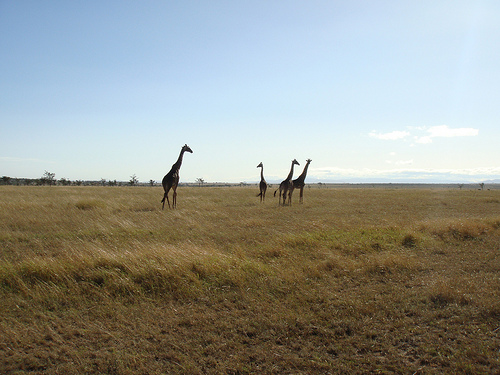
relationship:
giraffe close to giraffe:
[290, 157, 314, 206] [270, 151, 297, 203]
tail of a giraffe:
[272, 182, 281, 196] [275, 158, 300, 205]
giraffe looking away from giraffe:
[255, 160, 271, 201] [277, 149, 298, 207]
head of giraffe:
[179, 142, 193, 156] [159, 134, 200, 206]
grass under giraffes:
[2, 184, 498, 371] [155, 138, 318, 208]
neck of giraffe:
[170, 153, 191, 167] [159, 138, 197, 208]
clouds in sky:
[352, 114, 488, 150] [2, 2, 498, 194]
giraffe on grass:
[157, 133, 195, 209] [2, 184, 498, 371]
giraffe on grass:
[255, 160, 271, 201] [2, 184, 498, 371]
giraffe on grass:
[269, 159, 303, 207] [2, 184, 498, 371]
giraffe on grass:
[290, 154, 319, 206] [2, 184, 498, 371]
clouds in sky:
[364, 130, 416, 148] [2, 2, 498, 194]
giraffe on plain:
[157, 142, 195, 209] [159, 140, 197, 216]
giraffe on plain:
[255, 160, 275, 196] [2, 184, 489, 369]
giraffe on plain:
[269, 159, 303, 207] [2, 184, 489, 369]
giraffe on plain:
[255, 160, 271, 201] [2, 184, 489, 369]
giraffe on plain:
[282, 154, 303, 201] [2, 184, 489, 369]